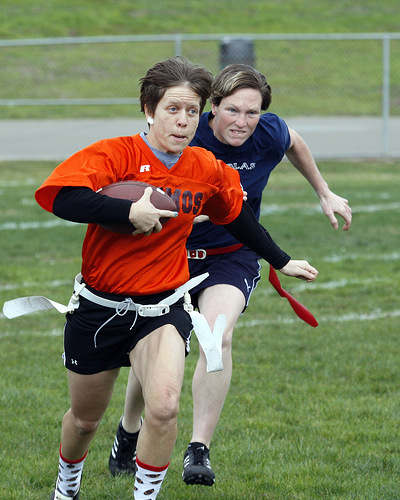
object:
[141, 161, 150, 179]
letter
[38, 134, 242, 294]
shirt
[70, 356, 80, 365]
emblem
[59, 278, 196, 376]
shorts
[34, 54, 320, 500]
player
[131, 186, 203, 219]
letters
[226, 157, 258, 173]
letters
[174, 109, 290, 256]
shirt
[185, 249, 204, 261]
belt fastener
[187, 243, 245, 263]
belt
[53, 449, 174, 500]
socks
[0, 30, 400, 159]
fence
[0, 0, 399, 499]
background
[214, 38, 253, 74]
garbage can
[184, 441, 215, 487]
stripes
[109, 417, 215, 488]
cleats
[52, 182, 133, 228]
sleeve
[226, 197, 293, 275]
sleeve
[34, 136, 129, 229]
arm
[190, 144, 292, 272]
arm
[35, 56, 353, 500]
person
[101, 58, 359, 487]
person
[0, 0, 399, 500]
grass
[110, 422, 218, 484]
shoes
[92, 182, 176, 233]
ball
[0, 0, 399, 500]
photo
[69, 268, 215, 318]
belt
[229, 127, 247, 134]
teeth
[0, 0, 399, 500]
football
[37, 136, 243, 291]
orange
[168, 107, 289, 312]
blue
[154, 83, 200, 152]
face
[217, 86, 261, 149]
face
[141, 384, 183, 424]
knee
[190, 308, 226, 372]
flag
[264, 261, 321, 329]
flag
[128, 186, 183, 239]
hand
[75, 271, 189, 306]
waist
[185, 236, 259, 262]
waist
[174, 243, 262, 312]
shorts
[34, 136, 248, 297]
jersey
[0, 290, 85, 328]
flags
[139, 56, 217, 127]
hair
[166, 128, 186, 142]
grimace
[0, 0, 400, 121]
field